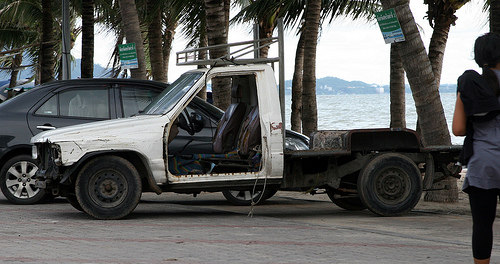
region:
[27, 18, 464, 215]
a parked bare bones beach buggy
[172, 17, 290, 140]
a rack for beach equipment on the cab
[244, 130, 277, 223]
door and seat belt combination on the cab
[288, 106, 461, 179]
the exposed bed of the truck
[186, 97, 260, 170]
the seats are torn and stuffing exposed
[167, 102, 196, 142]
the steering wheel on the pick up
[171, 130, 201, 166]
a black gear shift knob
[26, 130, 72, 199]
a bumper is missing from the front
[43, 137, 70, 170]
headlamp is missing from the truck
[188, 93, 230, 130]
an object is hanging inside the cab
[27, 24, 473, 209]
broken-down white pickup truck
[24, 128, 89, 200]
front bumper missing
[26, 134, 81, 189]
one headlight missing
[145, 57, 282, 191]
no door on white car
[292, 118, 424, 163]
rusty iron back section of truck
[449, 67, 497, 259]
woman with black sweatshirt draped over shoulder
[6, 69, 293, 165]
black car parked next to broken-down truck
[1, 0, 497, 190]
row of palm trees behind parked cars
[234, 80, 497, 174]
view of water behind palm trees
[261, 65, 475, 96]
view of mountains behind water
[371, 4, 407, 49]
green and white sign on tree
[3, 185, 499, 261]
red lines on pavement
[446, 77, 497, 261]
woman in black capri pants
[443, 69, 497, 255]
woman in gray T-shirt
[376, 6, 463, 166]
front tree leaning slightly forward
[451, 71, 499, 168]
sweater draped over left shoulder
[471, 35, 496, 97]
woman with black ponytail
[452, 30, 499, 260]
partial view of woman on right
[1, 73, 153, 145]
black car with silver handle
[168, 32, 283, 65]
silver bars on truck roof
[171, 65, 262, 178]
A truck with no door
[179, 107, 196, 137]
The steering wheel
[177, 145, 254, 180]
A bue blanket on the set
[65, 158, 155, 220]
The front tire.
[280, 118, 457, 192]
The flat bed of the truck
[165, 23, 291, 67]
A roof rack on the truck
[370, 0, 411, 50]
A sign on the tree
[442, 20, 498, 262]
A women stands in the corner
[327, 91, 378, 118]
Waves on the water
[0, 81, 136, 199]
A black car parked behind the truck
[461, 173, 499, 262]
woman's pants are black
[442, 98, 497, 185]
woman's shirt is gray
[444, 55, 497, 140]
woman holding jacket over shoulder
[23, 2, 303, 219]
the truck is white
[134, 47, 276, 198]
truck has no doors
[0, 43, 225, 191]
the car is black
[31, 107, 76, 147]
door has silver handles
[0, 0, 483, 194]
palm trees behind cars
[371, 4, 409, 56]
sign is green and white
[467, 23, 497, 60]
woman's hair is black